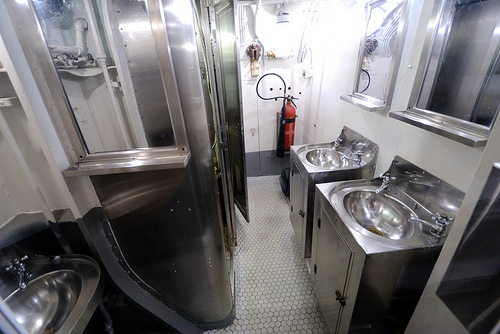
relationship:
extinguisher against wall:
[255, 73, 297, 153] [234, 8, 317, 168]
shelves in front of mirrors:
[338, 87, 493, 160] [369, 9, 493, 127]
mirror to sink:
[27, 0, 181, 158] [0, 242, 112, 332]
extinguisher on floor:
[255, 73, 297, 153] [202, 173, 326, 333]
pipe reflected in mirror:
[72, 7, 145, 142] [6, 2, 219, 204]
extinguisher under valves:
[255, 73, 297, 153] [249, 40, 308, 77]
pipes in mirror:
[25, 20, 127, 92] [44, 9, 194, 177]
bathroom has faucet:
[0, 0, 499, 330] [408, 211, 454, 241]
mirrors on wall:
[354, 2, 498, 148] [312, 1, 498, 194]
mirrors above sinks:
[354, 2, 498, 148] [272, 121, 442, 263]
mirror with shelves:
[410, 3, 497, 138] [338, 97, 493, 137]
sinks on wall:
[272, 121, 442, 263] [319, 9, 487, 216]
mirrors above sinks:
[354, 2, 498, 148] [296, 118, 456, 248]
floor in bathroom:
[244, 178, 319, 328] [0, 0, 499, 330]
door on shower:
[216, 0, 252, 230] [11, 0, 246, 326]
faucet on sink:
[3, 253, 32, 289] [0, 252, 99, 332]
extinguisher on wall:
[255, 73, 297, 153] [232, 0, 309, 153]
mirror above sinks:
[410, 3, 497, 138] [268, 123, 462, 332]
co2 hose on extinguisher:
[255, 72, 297, 108] [256, 72, 299, 157]